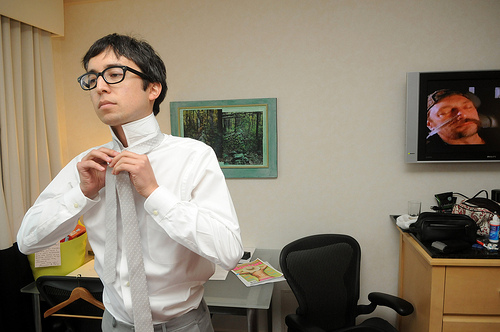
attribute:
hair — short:
[76, 33, 170, 80]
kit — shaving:
[413, 213, 480, 243]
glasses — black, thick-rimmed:
[78, 66, 138, 89]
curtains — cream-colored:
[0, 14, 85, 284]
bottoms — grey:
[103, 290, 208, 330]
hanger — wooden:
[40, 271, 108, 321]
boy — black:
[1, 34, 263, 330]